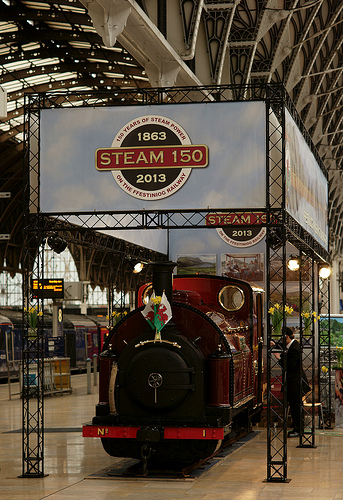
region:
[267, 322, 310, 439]
man standing next to a train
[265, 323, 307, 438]
man wearing a black shirt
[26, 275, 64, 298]
yellow letters on a black sign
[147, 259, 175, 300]
black smokestack on a red train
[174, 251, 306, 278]
three paintings hanging on the wall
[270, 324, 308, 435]
man standing in front of paintings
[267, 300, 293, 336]
yellow flowers above man wearing black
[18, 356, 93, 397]
carts next to white and blue pole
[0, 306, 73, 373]
blue train above black sign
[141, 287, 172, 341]
two green, white, and red flags on train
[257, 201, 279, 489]
This is a pole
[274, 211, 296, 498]
This is a pole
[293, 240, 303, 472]
This is a pole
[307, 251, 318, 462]
This is a pole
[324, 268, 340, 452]
This is a pole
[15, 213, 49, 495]
This is a pole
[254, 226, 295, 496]
This is a pole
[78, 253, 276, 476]
Red, black and gold train.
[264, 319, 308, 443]
Man in black near train.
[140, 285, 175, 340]
Two flags with dragons on them.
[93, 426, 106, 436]
Gold colored 'N' on train.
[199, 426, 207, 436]
Gold colored 'I' on train.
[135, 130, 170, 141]
'1863' in yellow on black background.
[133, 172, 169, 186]
'2013' in yellow on front sign.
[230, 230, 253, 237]
'2013' in yellow on back sign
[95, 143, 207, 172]
Red and gold front sign that says 'STEAM 150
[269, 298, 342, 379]
Yellow flowers on side of train display.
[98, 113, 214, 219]
red black and white sign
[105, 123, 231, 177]
sign on background of clouds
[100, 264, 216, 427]
black train under sign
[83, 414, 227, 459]
red stripe on train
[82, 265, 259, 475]
red train on brown floor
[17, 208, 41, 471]
black poles supporting sign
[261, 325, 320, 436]
man is next to train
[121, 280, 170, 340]
two Wales flags on train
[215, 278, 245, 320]
circular window on train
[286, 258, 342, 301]
white lights behind train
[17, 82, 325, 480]
A steam engine display.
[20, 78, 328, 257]
A canopy above the steam engine.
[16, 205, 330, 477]
Black metal support beams holding the canopy.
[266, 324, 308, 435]
A man wearing a black suit.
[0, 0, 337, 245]
Metal beams on the ceiling.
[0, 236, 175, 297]
Glass windows along the wall.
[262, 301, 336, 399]
Flower pots with yellow flowers.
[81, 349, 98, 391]
Two metal poles with blue tops.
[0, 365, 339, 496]
A tan tiled floor.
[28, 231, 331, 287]
Lights attached to black metal beams.